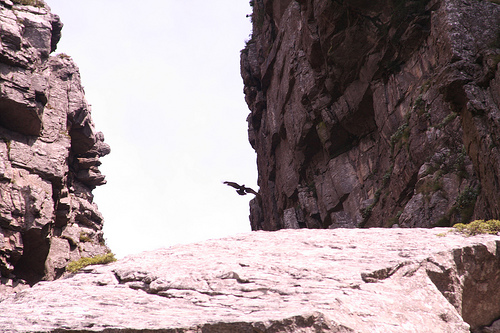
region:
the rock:
[92, 217, 289, 307]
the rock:
[133, 121, 267, 281]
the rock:
[213, 147, 303, 326]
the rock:
[261, 202, 322, 306]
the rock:
[259, 238, 278, 320]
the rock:
[267, 263, 304, 323]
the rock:
[245, 228, 312, 320]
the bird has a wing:
[220, 171, 240, 191]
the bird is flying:
[211, 174, 259, 206]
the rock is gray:
[203, 249, 310, 307]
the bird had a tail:
[234, 189, 247, 204]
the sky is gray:
[119, 171, 185, 229]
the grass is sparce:
[440, 219, 496, 240]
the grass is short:
[58, 249, 120, 275]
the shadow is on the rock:
[15, 224, 65, 275]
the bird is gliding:
[214, 176, 256, 201]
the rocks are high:
[8, 0, 126, 252]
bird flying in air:
[233, 181, 255, 213]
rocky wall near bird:
[242, 42, 456, 221]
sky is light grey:
[113, 7, 262, 167]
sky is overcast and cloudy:
[94, 9, 199, 164]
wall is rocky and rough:
[9, 10, 99, 256]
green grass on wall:
[51, 243, 126, 290]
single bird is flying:
[223, 168, 261, 209]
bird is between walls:
[220, 181, 254, 209]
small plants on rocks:
[64, 253, 131, 278]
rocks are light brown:
[83, 240, 445, 311]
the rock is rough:
[73, 100, 274, 317]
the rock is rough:
[138, 160, 232, 306]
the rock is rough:
[195, 194, 286, 321]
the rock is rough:
[168, 101, 327, 327]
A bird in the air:
[212, 158, 274, 207]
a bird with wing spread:
[218, 178, 262, 214]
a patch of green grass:
[48, 240, 125, 281]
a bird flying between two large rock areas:
[0, 6, 496, 266]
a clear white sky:
[59, 11, 276, 254]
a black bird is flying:
[219, 163, 276, 225]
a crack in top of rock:
[104, 261, 274, 331]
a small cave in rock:
[5, 220, 62, 290]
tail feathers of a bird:
[234, 186, 250, 196]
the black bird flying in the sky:
[217, 168, 269, 219]